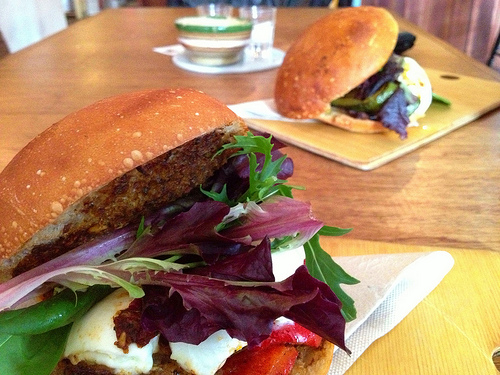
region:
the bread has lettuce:
[266, 1, 445, 138]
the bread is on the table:
[0, 3, 460, 374]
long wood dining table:
[0, 7, 497, 373]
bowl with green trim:
[176, 16, 251, 68]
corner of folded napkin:
[335, 250, 456, 373]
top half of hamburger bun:
[0, 87, 245, 269]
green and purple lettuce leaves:
[0, 134, 358, 373]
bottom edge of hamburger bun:
[323, 114, 388, 133]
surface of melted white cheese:
[65, 292, 154, 372]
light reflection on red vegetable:
[229, 328, 320, 373]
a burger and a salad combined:
[67, 87, 356, 369]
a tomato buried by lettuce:
[54, 194, 365, 371]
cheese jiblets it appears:
[60, 193, 363, 368]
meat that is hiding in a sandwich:
[16, 85, 294, 374]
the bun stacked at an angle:
[271, 3, 444, 145]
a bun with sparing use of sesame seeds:
[0, 75, 242, 255]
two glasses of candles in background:
[1, 0, 498, 143]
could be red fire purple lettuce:
[110, 193, 352, 361]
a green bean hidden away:
[2, 251, 141, 367]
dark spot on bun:
[275, 8, 395, 113]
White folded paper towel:
[318, 246, 461, 374]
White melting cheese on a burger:
[66, 285, 166, 374]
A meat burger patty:
[8, 128, 243, 282]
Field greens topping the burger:
[0, 143, 307, 363]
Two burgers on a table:
[0, 3, 462, 373]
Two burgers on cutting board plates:
[8, 8, 486, 374]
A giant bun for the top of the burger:
[273, 8, 408, 129]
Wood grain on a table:
[316, 171, 497, 236]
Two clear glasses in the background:
[192, 5, 278, 64]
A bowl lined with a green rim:
[175, 12, 250, 40]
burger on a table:
[23, 102, 388, 372]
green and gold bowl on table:
[153, 9, 258, 74]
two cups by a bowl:
[201, 8, 286, 50]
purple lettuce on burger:
[107, 227, 343, 350]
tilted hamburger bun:
[27, 85, 243, 263]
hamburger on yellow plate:
[206, 32, 496, 154]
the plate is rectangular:
[221, 80, 493, 164]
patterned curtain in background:
[381, 5, 498, 52]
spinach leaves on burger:
[6, 292, 101, 369]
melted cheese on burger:
[68, 287, 228, 371]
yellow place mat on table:
[415, 328, 457, 355]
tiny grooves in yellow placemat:
[440, 293, 471, 334]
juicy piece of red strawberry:
[241, 343, 301, 372]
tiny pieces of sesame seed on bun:
[274, 68, 309, 91]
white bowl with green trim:
[175, 12, 260, 39]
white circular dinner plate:
[158, 45, 286, 79]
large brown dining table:
[361, 173, 470, 215]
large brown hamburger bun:
[276, 11, 398, 104]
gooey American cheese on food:
[81, 305, 206, 368]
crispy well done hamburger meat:
[141, 169, 196, 190]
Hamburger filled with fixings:
[2, 83, 427, 374]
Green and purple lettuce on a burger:
[2, 133, 375, 373]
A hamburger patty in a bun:
[6, 126, 242, 276]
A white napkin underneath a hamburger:
[286, 241, 456, 371]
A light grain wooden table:
[3, 2, 498, 258]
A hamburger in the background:
[233, 1, 497, 176]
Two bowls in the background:
[157, 11, 274, 79]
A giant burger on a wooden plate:
[224, 6, 498, 174]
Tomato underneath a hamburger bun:
[215, 313, 331, 374]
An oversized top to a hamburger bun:
[266, 1, 397, 121]